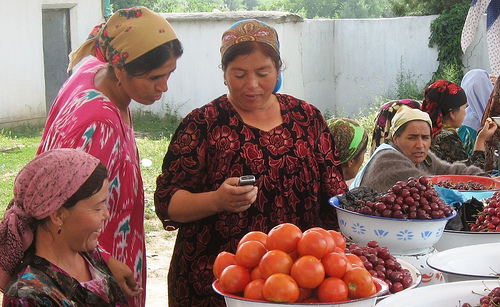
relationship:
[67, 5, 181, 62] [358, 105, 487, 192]
headband on woman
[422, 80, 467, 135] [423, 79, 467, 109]
headband on head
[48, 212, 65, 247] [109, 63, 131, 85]
earring on ear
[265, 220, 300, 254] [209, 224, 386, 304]
tomato in bowl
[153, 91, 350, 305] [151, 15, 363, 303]
dress on woman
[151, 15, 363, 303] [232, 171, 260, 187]
woman using phone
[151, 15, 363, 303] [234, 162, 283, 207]
woman looking at cell phone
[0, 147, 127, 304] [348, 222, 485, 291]
woman behind table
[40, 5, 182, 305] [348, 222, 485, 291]
woman behind table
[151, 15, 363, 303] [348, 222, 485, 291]
woman behind table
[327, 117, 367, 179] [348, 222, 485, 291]
woman behind table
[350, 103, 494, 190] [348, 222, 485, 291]
woman behind table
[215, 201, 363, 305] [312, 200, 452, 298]
tomatoes on table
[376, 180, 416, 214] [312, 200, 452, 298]
grapes on table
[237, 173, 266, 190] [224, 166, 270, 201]
phone in hand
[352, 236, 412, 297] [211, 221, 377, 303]
grapes behind tomatoes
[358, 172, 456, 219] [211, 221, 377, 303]
grapes behind tomatoes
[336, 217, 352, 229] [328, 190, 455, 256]
designs on bowl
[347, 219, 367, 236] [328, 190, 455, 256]
designs on bowl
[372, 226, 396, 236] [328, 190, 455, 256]
designs on bowl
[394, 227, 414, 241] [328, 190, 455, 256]
designs on bowl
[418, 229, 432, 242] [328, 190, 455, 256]
designs on bowl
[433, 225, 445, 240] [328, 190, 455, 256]
designs on bowl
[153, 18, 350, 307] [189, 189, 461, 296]
woman around table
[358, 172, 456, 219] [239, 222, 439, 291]
grapes on table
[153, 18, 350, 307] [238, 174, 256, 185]
woman looking phone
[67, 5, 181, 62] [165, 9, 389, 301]
headband on women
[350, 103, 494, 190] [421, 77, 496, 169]
woman talking woman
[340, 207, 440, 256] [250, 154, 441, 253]
bowls on table